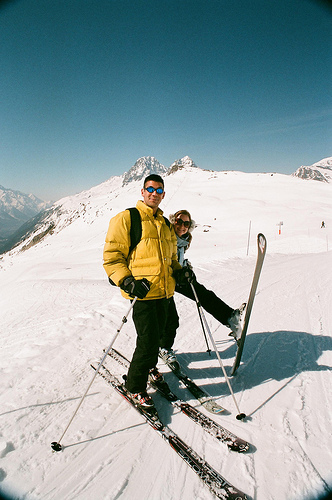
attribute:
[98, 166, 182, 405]
skier — male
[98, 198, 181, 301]
parka — yellow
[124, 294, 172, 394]
pants — black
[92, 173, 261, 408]
skier — man, woman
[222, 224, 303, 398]
ski — vertical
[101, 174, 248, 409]
skiers — posing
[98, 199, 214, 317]
jacket — bright, yellow, ski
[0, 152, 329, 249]
mountain — sloped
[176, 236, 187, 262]
jacket — light, blue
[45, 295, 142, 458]
pole — long, skinny, ski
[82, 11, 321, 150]
sky — clear, blue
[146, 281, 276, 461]
pole — ski pole, metal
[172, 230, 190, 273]
jacket — blue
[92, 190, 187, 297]
jacket — yellow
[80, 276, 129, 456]
ski pole — aluminum ski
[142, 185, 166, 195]
goggles — blue, reflective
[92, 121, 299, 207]
mountain — ski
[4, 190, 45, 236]
mountain — snow, covered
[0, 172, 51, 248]
mountain — hazy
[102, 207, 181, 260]
jacket — bright, yellow, puffy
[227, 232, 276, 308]
skis — downhill snow , pair 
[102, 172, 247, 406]
people — skiing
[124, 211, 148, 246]
strap — black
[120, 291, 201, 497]
black pants — pair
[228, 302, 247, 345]
foot — in air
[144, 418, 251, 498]
ski — black, brown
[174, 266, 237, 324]
pants —  black ski 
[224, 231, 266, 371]
skis — K2 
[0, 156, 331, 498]
snow — white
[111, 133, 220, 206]
outcrops — rocky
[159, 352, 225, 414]
ski — light colored